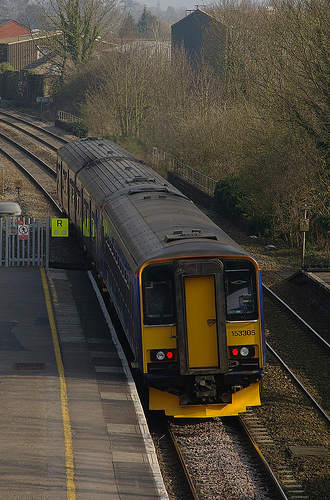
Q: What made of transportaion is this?
A: Train.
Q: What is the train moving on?
A: Tracks.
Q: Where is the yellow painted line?
A: On the train platform.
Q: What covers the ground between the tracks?
A: Gravel.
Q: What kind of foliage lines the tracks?
A: Trees.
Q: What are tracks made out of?
A: Metal.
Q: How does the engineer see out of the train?
A: Windows.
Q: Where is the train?
A: By the platform.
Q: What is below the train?
A: Train tracks.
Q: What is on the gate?
A: A sign.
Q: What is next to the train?
A: Trees.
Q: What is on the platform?
A: Painted lines.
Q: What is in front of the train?
A: A door.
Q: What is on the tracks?
A: Gravel.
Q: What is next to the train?
A: Another track.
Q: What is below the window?
A: A number.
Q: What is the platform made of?
A: Concrete.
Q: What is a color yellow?
A: A caution line.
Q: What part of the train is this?
A: Front end.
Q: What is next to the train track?
A: Trees.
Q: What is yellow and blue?
A: A train.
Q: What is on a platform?
A: A line.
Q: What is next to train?
A: A white line.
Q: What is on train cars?
A: Black roof.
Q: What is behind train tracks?
A: Trees.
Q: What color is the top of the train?
A: Black.